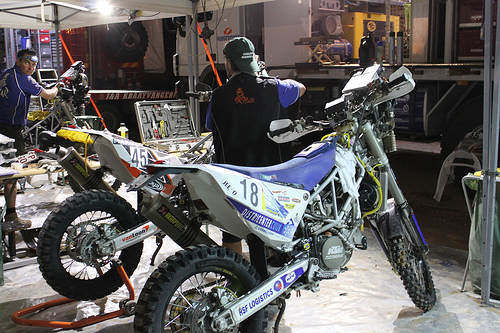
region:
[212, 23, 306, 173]
a man standing near a motorcycle.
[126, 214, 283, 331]
a wheel on a motorcycle.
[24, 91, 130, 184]
the back of a motorcycle.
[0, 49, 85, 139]
a man looking at a motorcycle.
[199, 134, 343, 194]
a seat on a motorcycle.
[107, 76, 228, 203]
a tool box in a garage.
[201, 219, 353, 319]
a chain case for a motorcycle.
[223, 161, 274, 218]
the number 18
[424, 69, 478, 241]
a person standing in a garage.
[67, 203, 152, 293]
chain holders on a bike.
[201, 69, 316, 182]
Black and blue shirt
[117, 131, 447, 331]
A blue and white bike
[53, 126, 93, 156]
Yellow rope on back of bike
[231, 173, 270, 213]
Number 18 on bike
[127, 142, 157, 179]
Number 45 on bike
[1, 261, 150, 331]
Orange metal bar holding bike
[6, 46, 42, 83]
Goggles on man's forehead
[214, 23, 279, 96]
Black hat with white letters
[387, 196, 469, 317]
Front tire of bike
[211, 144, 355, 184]
Blue seat on bike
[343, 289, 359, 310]
part of a floor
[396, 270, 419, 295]
part of a wheel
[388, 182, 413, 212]
part of a metal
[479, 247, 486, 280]
part of a metal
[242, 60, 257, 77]
edge of a cap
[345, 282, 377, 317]
part of a floor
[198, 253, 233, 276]
edge of a wheel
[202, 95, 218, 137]
edge of a coat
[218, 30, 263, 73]
Person wearing a cap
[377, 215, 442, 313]
Wheel of a motorcycle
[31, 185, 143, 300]
Back wheel of a motorcycle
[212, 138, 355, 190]
Seat of a motorcycle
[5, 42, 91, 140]
Man working on a motorcycle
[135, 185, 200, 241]
Muffler of a motorcycle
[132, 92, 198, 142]
Tools in a box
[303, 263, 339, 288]
Footrest on a motorcycle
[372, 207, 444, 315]
Motorcycle wheel with shock absorbers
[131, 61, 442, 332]
Motorcycle in a shop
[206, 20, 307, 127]
man with black cap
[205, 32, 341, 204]
man with black cap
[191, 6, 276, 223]
man with black cap